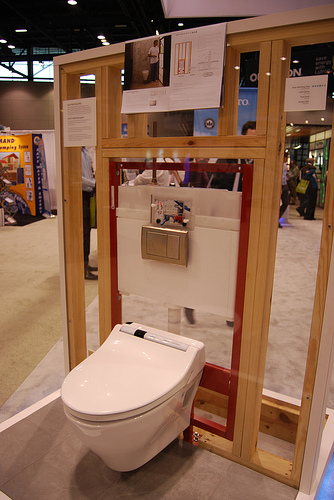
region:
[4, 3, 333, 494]
a scene inside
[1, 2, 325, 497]
a scene at an exhibit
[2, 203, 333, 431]
a gray floor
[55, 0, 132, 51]
some lights on the building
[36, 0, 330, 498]
a wood frame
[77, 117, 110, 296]
a person seen through the frame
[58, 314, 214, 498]
a restroom toilet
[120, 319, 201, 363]
back of white toliet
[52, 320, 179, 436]
top of closed toliet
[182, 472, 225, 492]
grey tile on floor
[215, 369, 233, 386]
red wood of door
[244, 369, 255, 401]
tan wood of door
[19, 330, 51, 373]
beige rug on floor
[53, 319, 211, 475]
The toilet is white.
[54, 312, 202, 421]
The lid is down.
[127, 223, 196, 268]
The switch is silver.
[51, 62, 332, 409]
The frame is wood.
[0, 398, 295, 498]
The ground is gray.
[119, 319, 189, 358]
The toilets have buttons.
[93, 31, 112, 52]
The lights are on.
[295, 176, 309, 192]
Her purse is green.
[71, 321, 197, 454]
A toilet in the hardware store.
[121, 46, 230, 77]
photo on the wood stand.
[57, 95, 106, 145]
Paper on the wood stand.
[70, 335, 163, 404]
The toilet seat is down.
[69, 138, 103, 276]
a person standing behind the stand.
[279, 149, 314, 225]
People shopping in the home store.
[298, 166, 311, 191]
The person is holding a green shopping bag.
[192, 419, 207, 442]
Screw on the wood plank.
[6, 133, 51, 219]
A display sign on the corner.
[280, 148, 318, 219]
People standing around in the store.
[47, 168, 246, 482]
a toilet set up on the display floor of a store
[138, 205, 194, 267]
the flushing lever is mounted on center of the tank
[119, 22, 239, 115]
picture and diagram of how toilet will work and look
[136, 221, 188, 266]
flusher is stainless steel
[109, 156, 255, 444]
red steel frame holds the fixtures in place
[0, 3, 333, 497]
fixtures and frame are mounted to a wood frame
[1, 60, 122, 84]
windows are seen high on the display floor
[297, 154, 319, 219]
person carries a large green bag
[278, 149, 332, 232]
people look at a separate display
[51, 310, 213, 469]
a white auto toilet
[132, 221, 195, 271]
a silver mounter panel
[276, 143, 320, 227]
people in the background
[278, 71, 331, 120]
a mounted piece of paper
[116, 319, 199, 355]
buttons on the toilet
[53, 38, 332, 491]
wooden frame with toilet attached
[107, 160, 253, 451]
red frame supporting toilet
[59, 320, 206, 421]
white toilet seat lid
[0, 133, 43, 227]
large orange advertisement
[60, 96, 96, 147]
small white info panel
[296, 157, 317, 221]
woman with green bag walking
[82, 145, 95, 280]
man in black pants with blue shirt tucked in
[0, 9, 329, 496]
toilet display at convention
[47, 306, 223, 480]
white toilet behind wood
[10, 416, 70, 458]
A tile in a floor.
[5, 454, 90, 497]
A tile in a floor.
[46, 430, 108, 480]
A tile in a floor.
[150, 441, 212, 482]
A tile in a floor.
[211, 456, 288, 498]
A tile in a floor.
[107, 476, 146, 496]
A tile in a floor.